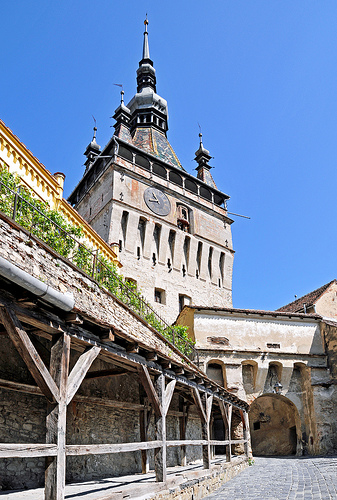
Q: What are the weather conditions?
A: It is clear.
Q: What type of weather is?
A: It is clear.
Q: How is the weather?
A: It is clear.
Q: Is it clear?
A: Yes, it is clear.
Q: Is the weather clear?
A: Yes, it is clear.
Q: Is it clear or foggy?
A: It is clear.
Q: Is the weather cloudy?
A: No, it is clear.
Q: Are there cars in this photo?
A: No, there are no cars.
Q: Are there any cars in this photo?
A: No, there are no cars.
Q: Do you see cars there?
A: No, there are no cars.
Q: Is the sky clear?
A: Yes, the sky is clear.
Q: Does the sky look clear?
A: Yes, the sky is clear.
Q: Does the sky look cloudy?
A: No, the sky is clear.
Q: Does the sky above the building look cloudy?
A: No, the sky is clear.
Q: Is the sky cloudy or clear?
A: The sky is clear.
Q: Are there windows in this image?
A: Yes, there is a window.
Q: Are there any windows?
A: Yes, there is a window.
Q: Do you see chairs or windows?
A: Yes, there is a window.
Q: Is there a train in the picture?
A: No, there are no trains.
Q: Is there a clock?
A: Yes, there is a clock.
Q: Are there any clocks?
A: Yes, there is a clock.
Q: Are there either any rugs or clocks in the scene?
A: Yes, there is a clock.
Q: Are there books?
A: No, there are no books.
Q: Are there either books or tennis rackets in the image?
A: No, there are no books or tennis rackets.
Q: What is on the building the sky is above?
A: The clock is on the building.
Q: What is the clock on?
A: The clock is on the building.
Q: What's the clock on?
A: The clock is on the building.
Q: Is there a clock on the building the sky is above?
A: Yes, there is a clock on the building.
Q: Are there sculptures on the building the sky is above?
A: No, there is a clock on the building.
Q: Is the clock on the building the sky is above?
A: Yes, the clock is on the building.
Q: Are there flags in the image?
A: Yes, there is a flag.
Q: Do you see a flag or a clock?
A: Yes, there is a flag.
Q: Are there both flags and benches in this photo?
A: No, there is a flag but no benches.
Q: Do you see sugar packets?
A: No, there are no sugar packets.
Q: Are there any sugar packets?
A: No, there are no sugar packets.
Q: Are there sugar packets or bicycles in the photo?
A: No, there are no sugar packets or bicycles.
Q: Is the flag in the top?
A: Yes, the flag is in the top of the image.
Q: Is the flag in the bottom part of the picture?
A: No, the flag is in the top of the image.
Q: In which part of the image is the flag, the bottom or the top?
A: The flag is in the top of the image.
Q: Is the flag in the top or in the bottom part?
A: The flag is in the top of the image.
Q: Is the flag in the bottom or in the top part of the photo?
A: The flag is in the top of the image.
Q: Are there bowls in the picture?
A: No, there are no bowls.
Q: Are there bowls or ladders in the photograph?
A: No, there are no bowls or ladders.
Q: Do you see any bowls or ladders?
A: No, there are no bowls or ladders.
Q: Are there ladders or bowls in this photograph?
A: No, there are no bowls or ladders.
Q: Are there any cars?
A: No, there are no cars.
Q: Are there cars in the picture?
A: No, there are no cars.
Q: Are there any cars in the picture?
A: No, there are no cars.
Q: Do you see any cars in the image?
A: No, there are no cars.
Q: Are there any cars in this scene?
A: No, there are no cars.